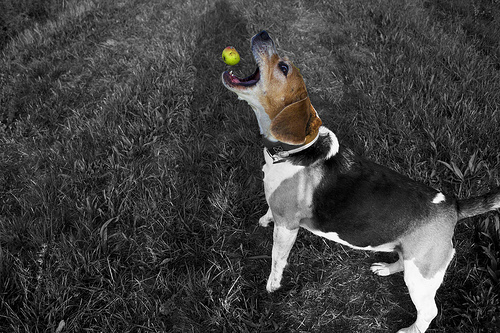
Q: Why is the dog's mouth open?
A: To catch the treat.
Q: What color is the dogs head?
A: Brown.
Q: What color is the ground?
A: Gray.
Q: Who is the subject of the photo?
A: The dog.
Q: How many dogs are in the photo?
A: 1.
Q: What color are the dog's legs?
A: White.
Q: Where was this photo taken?
A: In a field.